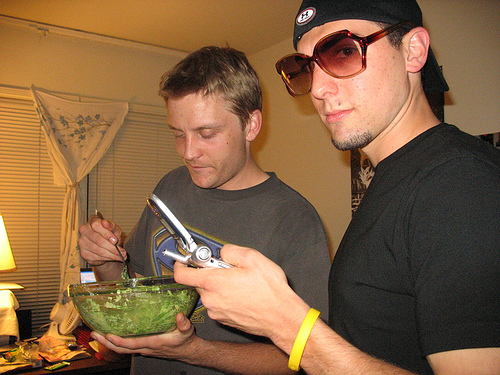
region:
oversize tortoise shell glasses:
[267, 33, 372, 97]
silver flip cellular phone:
[142, 185, 272, 335]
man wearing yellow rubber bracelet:
[282, 290, 321, 374]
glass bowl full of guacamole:
[67, 271, 197, 334]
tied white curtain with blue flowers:
[32, 83, 132, 206]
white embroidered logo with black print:
[292, 5, 315, 25]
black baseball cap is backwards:
[289, 0, 456, 74]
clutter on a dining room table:
[1, 329, 103, 374]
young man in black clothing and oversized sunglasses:
[269, 4, 491, 374]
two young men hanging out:
[49, 3, 495, 373]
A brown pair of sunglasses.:
[277, 17, 414, 98]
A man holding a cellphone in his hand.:
[143, 0, 497, 374]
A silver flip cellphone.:
[144, 194, 232, 273]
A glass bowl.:
[69, 275, 201, 337]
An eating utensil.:
[101, 224, 141, 281]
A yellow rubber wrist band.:
[289, 299, 320, 372]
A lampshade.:
[1, 215, 18, 276]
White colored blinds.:
[0, 93, 186, 337]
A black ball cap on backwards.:
[292, 3, 465, 94]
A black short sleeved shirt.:
[324, 127, 496, 372]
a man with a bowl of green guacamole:
[61, 40, 318, 370]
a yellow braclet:
[286, 308, 321, 372]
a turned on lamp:
[0, 211, 17, 293]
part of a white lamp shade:
[0, 215, 19, 274]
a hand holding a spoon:
[79, 208, 139, 278]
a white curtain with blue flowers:
[22, 79, 132, 330]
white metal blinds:
[0, 109, 179, 309]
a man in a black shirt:
[272, 0, 498, 372]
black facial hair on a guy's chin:
[329, 131, 369, 151]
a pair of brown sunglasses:
[278, 25, 404, 96]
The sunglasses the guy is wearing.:
[273, 26, 408, 88]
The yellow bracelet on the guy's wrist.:
[276, 302, 322, 367]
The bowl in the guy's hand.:
[74, 268, 195, 335]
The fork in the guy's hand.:
[94, 199, 149, 285]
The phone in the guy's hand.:
[149, 190, 244, 281]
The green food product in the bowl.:
[77, 280, 187, 335]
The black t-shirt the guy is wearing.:
[341, 141, 494, 356]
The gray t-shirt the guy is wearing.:
[128, 148, 324, 353]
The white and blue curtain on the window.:
[24, 83, 118, 343]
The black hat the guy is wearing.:
[278, 5, 441, 66]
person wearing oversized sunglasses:
[208, 6, 495, 370]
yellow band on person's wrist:
[272, 298, 329, 364]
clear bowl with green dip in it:
[71, 271, 203, 333]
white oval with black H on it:
[290, 8, 319, 25]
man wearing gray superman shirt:
[54, 50, 329, 374]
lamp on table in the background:
[0, 219, 37, 349]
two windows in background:
[12, 95, 200, 328]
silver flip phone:
[150, 190, 268, 269]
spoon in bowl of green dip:
[96, 196, 143, 298]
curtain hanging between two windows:
[26, 78, 123, 349]